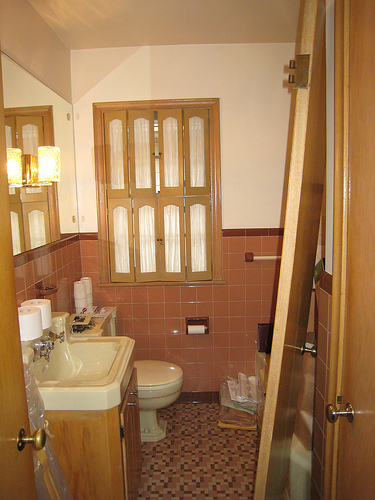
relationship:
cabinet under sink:
[38, 341, 142, 499] [20, 310, 137, 409]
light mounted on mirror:
[36, 144, 61, 184] [1, 51, 81, 255]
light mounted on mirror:
[5, 148, 23, 187] [1, 51, 81, 255]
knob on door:
[290, 340, 317, 363] [330, 0, 372, 499]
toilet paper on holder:
[186, 325, 205, 335] [184, 316, 214, 342]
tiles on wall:
[178, 280, 291, 346] [69, 44, 294, 402]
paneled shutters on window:
[101, 107, 213, 282] [100, 107, 213, 283]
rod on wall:
[243, 250, 281, 261] [156, 206, 324, 424]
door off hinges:
[252, 1, 331, 499] [287, 56, 308, 88]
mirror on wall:
[0, 51, 80, 256] [225, 42, 278, 128]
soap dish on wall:
[35, 280, 62, 297] [23, 262, 59, 285]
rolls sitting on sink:
[18, 293, 56, 343] [37, 331, 136, 409]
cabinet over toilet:
[90, 95, 227, 291] [96, 309, 189, 420]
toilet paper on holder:
[188, 325, 206, 335] [185, 323, 209, 329]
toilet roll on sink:
[17, 304, 48, 340] [19, 331, 136, 409]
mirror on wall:
[1, 51, 81, 255] [1, 2, 81, 274]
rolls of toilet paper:
[18, 299, 52, 341] [4, 280, 76, 359]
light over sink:
[5, 148, 23, 187] [36, 334, 133, 405]